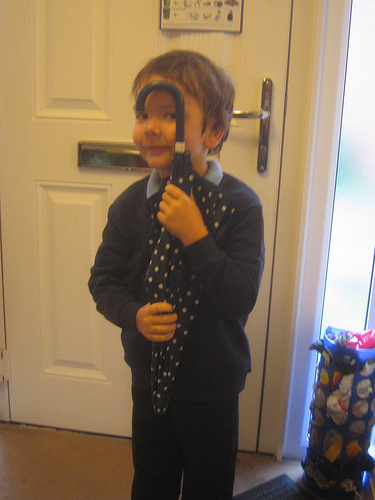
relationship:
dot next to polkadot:
[159, 282, 163, 289] [155, 280, 163, 290]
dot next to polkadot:
[159, 282, 163, 289] [170, 245, 178, 255]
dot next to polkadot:
[159, 282, 163, 289] [166, 274, 170, 278]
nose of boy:
[140, 123, 165, 137] [75, 69, 259, 496]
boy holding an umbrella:
[88, 48, 265, 499] [135, 79, 237, 416]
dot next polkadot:
[159, 282, 163, 289] [160, 240, 172, 250]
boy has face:
[88, 48, 265, 499] [132, 68, 207, 170]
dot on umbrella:
[159, 282, 163, 289] [135, 79, 237, 416]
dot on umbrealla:
[159, 282, 163, 289] [118, 66, 240, 438]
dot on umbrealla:
[159, 282, 163, 289] [107, 58, 257, 441]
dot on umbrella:
[159, 282, 163, 289] [131, 68, 238, 440]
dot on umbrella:
[159, 282, 163, 289] [119, 68, 250, 457]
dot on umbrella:
[159, 282, 163, 289] [113, 72, 248, 425]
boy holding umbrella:
[88, 48, 265, 499] [131, 68, 238, 440]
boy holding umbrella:
[85, 40, 287, 496] [135, 79, 237, 416]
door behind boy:
[0, 0, 302, 458] [88, 48, 265, 499]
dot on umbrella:
[159, 282, 163, 289] [123, 77, 258, 436]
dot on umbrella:
[154, 277, 167, 292] [123, 77, 258, 436]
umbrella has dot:
[135, 79, 237, 416] [178, 302, 190, 316]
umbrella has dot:
[131, 68, 238, 440] [161, 268, 171, 280]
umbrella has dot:
[135, 79, 237, 416] [154, 251, 167, 261]